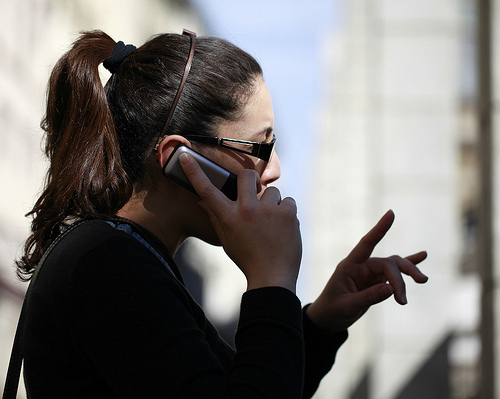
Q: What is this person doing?
A: Talking on the phone.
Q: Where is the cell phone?
A: In the person's right hand.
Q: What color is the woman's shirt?
A: Black.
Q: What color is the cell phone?
A: Silver.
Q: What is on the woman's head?
A: Headband.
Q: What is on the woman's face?
A: Glasses.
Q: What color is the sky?
A: Blue.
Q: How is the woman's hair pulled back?
A: In a ponytail.